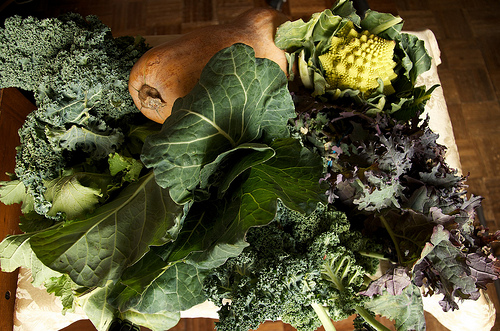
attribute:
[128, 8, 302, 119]
squash — large, orange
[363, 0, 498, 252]
flooring — wooden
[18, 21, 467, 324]
vegetables — light brown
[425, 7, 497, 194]
flooring — brown, laminate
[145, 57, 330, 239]
lettuce — green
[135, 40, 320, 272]
leaf — large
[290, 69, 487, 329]
leaves — purple, lettuce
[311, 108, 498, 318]
lettuce — purple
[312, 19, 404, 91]
vegetable — yellow, spiky 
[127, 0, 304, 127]
pumpkin — orange , small 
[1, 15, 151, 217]
broccoli sticks — green 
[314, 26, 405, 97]
vegetable — yellow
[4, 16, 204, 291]
vegetables — green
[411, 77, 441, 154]
plate — white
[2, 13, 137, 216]
broccolli — green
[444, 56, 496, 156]
table — small , brown 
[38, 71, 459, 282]
vegetables — healthy 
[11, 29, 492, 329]
fabric — white